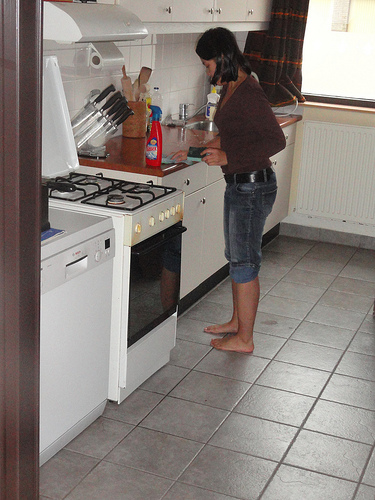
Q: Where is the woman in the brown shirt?
A: Kitchen.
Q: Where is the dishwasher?
A: Next to stove.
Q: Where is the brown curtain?
A: Over the window.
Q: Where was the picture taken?
A: In a kitchen.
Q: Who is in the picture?
A: A woman.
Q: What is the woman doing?
A: Cleaning.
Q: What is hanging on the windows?
A: Curtains.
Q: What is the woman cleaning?
A: The counters.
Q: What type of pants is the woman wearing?
A: Jeans.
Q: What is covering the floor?
A: Tile.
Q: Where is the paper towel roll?
A: On wall.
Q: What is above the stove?
A: A vent.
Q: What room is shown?
A: Kitchen.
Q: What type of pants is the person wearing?
A: Jeans.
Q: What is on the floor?
A: Tile.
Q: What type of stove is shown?
A: Gas.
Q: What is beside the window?
A: Curtain.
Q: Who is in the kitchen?
A: The woman.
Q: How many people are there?
A: 1.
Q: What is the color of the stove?
A: White.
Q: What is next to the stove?
A: Cleaner.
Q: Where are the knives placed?
A: Knife holder.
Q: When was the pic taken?
A: During the day.